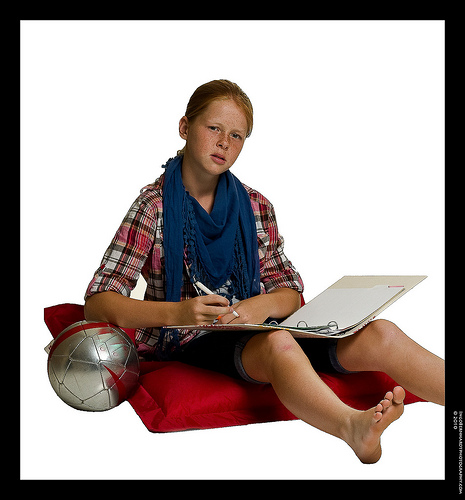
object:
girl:
[84, 79, 444, 462]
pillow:
[43, 302, 428, 431]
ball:
[45, 321, 140, 411]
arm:
[84, 203, 181, 323]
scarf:
[150, 156, 258, 361]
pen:
[193, 280, 241, 318]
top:
[194, 281, 198, 284]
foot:
[350, 385, 405, 464]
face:
[190, 102, 247, 175]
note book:
[162, 275, 426, 338]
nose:
[215, 132, 231, 151]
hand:
[179, 294, 234, 326]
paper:
[277, 285, 404, 332]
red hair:
[185, 80, 253, 137]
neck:
[181, 147, 220, 198]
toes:
[393, 386, 406, 406]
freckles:
[209, 132, 218, 144]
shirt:
[84, 174, 304, 359]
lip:
[211, 154, 226, 162]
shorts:
[175, 330, 351, 385]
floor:
[19, 18, 444, 481]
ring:
[327, 321, 339, 329]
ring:
[295, 321, 308, 330]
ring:
[268, 321, 277, 326]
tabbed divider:
[387, 284, 403, 289]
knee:
[266, 330, 297, 353]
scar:
[282, 344, 292, 353]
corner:
[44, 303, 65, 327]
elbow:
[82, 281, 115, 323]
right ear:
[178, 117, 188, 141]